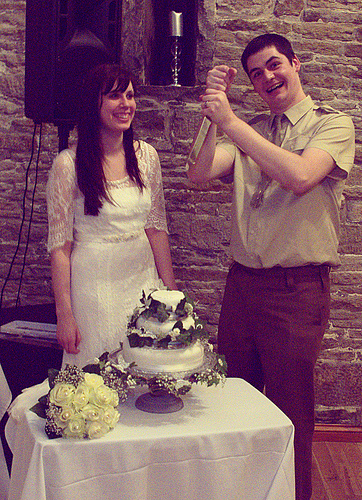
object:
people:
[45, 34, 354, 499]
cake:
[120, 286, 205, 375]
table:
[4, 377, 295, 499]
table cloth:
[5, 375, 296, 499]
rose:
[48, 373, 121, 441]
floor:
[309, 424, 362, 497]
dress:
[48, 139, 169, 373]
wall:
[0, 2, 361, 426]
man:
[185, 36, 355, 499]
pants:
[216, 262, 331, 500]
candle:
[168, 35, 187, 86]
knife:
[184, 115, 212, 173]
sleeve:
[46, 152, 74, 252]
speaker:
[24, 3, 122, 121]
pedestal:
[134, 380, 183, 415]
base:
[135, 393, 185, 412]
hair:
[73, 65, 147, 217]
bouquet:
[44, 366, 119, 438]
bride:
[45, 65, 171, 377]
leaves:
[206, 354, 227, 391]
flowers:
[44, 323, 227, 439]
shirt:
[217, 95, 357, 269]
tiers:
[122, 289, 208, 375]